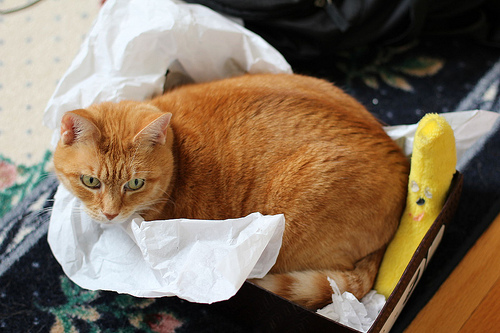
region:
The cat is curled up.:
[46, 59, 360, 279]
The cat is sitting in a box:
[20, 16, 285, 276]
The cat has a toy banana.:
[394, 79, 448, 281]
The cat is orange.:
[40, 31, 390, 263]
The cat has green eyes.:
[33, 110, 162, 197]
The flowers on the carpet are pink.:
[12, 221, 186, 329]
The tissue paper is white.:
[90, 192, 243, 293]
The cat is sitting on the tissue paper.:
[63, 65, 308, 324]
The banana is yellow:
[395, 81, 437, 246]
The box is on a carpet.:
[20, 50, 90, 326]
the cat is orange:
[54, 84, 381, 256]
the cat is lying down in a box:
[67, 110, 424, 280]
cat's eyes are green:
[70, 158, 159, 204]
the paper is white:
[62, 21, 308, 94]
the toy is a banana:
[386, 108, 443, 298]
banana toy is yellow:
[396, 107, 446, 304]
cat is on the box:
[65, 80, 412, 317]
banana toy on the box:
[350, 90, 472, 320]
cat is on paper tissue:
[69, 13, 404, 316]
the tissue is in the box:
[43, 29, 338, 239]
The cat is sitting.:
[63, 87, 440, 306]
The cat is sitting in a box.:
[46, 82, 446, 329]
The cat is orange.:
[153, 101, 377, 221]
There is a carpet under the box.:
[11, 200, 144, 330]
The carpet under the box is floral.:
[18, 226, 102, 328]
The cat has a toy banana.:
[377, 110, 472, 327]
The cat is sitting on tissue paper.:
[53, 24, 260, 300]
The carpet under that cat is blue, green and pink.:
[1, 224, 88, 328]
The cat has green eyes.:
[66, 166, 156, 200]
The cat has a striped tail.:
[243, 253, 381, 315]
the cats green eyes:
[75, 166, 141, 204]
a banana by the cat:
[373, 115, 453, 284]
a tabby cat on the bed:
[50, 71, 406, 291]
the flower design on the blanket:
[42, 279, 187, 331]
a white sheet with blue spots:
[10, 14, 73, 144]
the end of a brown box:
[328, 172, 467, 327]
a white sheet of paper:
[131, 222, 291, 302]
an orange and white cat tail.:
[271, 270, 368, 305]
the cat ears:
[58, 105, 174, 150]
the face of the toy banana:
[404, 177, 434, 232]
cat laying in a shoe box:
[22, 15, 458, 318]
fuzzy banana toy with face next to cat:
[370, 81, 455, 301]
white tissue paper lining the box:
[35, 30, 475, 315]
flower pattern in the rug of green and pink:
[2, 156, 178, 326]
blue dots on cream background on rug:
[5, 5, 95, 155]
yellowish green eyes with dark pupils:
[65, 160, 170, 201]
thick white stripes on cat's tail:
[250, 260, 380, 306]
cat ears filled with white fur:
[55, 96, 176, 151]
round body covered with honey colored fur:
[172, 55, 408, 265]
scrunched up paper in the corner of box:
[305, 270, 400, 328]